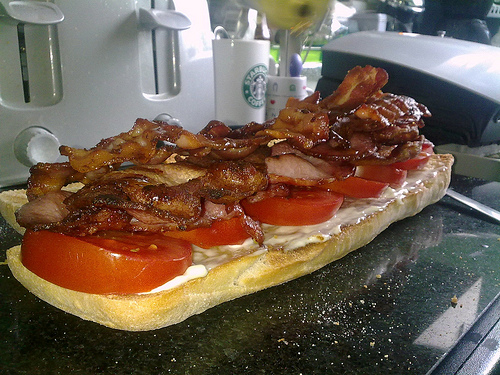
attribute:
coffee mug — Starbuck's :
[209, 37, 268, 128]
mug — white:
[207, 35, 272, 127]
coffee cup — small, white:
[264, 73, 314, 123]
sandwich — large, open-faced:
[10, 65, 471, 340]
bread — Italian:
[1, 153, 452, 336]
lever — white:
[142, 8, 197, 38]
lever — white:
[8, 4, 65, 26]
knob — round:
[14, 125, 61, 165]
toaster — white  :
[1, 0, 216, 186]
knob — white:
[11, 125, 61, 171]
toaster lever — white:
[135, 2, 187, 99]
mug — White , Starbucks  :
[204, 32, 273, 130]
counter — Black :
[402, 235, 492, 291]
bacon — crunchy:
[57, 106, 246, 202]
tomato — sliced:
[166, 218, 257, 248]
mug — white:
[211, 37, 269, 126]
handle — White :
[141, 3, 192, 42]